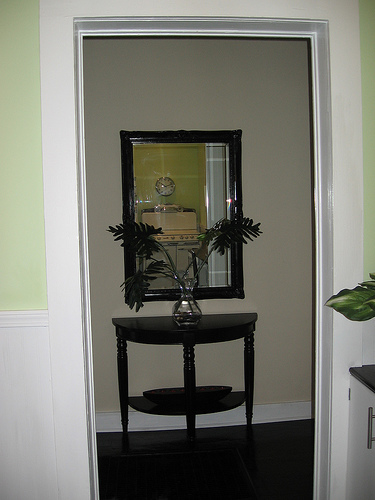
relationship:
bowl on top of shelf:
[142, 388, 230, 403] [128, 393, 246, 414]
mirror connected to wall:
[121, 128, 241, 301] [82, 36, 312, 435]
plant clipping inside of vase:
[108, 222, 192, 313] [168, 271, 201, 329]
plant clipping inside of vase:
[122, 261, 201, 315] [168, 271, 201, 329]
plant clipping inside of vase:
[181, 217, 262, 272] [168, 271, 201, 329]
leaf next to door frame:
[323, 273, 374, 322] [40, 1, 363, 499]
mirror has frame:
[121, 128, 241, 301] [119, 130, 241, 302]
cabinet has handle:
[346, 365, 374, 499] [367, 408, 374, 450]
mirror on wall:
[121, 128, 241, 301] [82, 36, 312, 435]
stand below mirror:
[113, 313, 255, 451] [121, 128, 241, 301]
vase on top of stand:
[168, 271, 201, 329] [113, 313, 255, 451]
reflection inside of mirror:
[142, 204, 200, 289] [121, 128, 241, 301]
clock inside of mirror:
[155, 177, 175, 196] [121, 128, 241, 301]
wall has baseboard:
[82, 36, 312, 435] [97, 402, 313, 433]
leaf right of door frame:
[323, 273, 374, 322] [40, 1, 363, 499]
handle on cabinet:
[367, 408, 374, 450] [346, 365, 374, 499]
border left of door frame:
[1, 310, 57, 499] [40, 1, 363, 499]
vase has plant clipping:
[168, 271, 201, 329] [108, 222, 192, 313]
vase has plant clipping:
[168, 271, 201, 329] [181, 217, 262, 272]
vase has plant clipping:
[168, 271, 201, 329] [122, 261, 201, 315]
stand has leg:
[113, 313, 255, 451] [120, 410, 131, 435]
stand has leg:
[113, 313, 255, 451] [187, 417, 195, 442]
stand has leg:
[113, 313, 255, 451] [245, 406, 255, 430]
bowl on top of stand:
[142, 388, 230, 403] [113, 313, 255, 451]